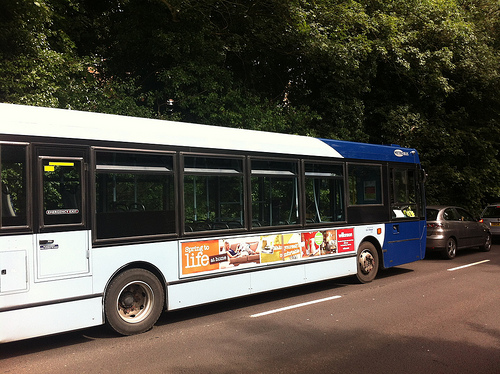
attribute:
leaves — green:
[16, 6, 491, 188]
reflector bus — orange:
[371, 227, 396, 237]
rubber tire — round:
[356, 240, 383, 280]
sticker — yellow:
[48, 160, 76, 165]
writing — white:
[336, 230, 351, 254]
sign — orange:
[181, 238, 219, 274]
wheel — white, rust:
[104, 264, 164, 335]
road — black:
[225, 292, 499, 367]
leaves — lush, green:
[312, 15, 431, 88]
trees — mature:
[61, 5, 477, 131]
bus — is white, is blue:
[0, 101, 430, 346]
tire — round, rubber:
[102, 265, 165, 335]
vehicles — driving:
[425, 201, 485, 259]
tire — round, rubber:
[355, 238, 381, 283]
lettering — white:
[180, 245, 219, 275]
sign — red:
[338, 227, 355, 252]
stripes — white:
[248, 243, 488, 366]